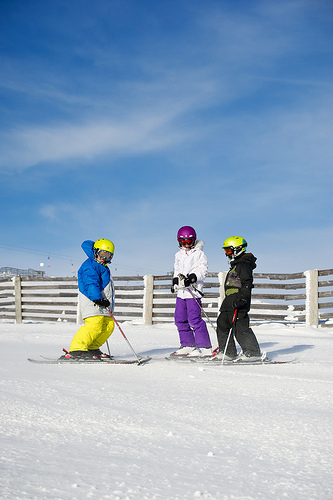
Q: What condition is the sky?
A: Clear.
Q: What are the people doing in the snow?
A: Skiing.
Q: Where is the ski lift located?
A: Background.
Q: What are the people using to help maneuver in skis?
A: Poles.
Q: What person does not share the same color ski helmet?
A: Middle.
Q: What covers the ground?
A: Snow.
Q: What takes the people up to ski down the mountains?
A: Lift.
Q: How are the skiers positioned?
A: Standing.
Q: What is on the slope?
A: 3 skiers.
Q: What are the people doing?
A: Taking a break.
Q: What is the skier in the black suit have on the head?
A: A yellow helmet.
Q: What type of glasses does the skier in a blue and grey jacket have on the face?
A: Goggles.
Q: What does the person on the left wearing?
A: Yellow pants.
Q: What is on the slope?
A: Snow.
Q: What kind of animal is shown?
A: None.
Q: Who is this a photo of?
A: People.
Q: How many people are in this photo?
A: Three.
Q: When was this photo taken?
A: Daytime.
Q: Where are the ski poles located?
A: In the people's hands.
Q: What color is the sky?
A: Blue.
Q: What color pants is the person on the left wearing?
A: Yellow.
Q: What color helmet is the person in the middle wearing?
A: Purple.